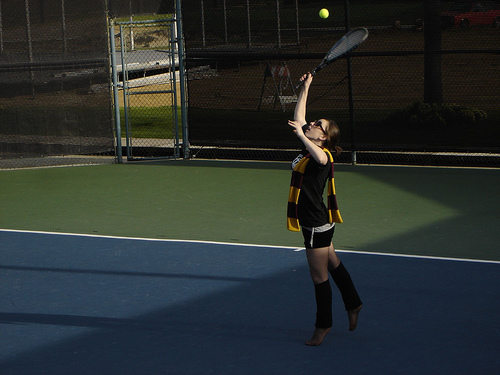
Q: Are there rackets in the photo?
A: Yes, there is a racket.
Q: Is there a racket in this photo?
A: Yes, there is a racket.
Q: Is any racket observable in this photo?
A: Yes, there is a racket.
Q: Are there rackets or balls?
A: Yes, there is a racket.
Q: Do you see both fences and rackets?
A: Yes, there are both a racket and a fence.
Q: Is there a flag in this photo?
A: No, there are no flags.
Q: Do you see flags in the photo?
A: No, there are no flags.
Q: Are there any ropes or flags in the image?
A: No, there are no flags or ropes.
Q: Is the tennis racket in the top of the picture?
A: Yes, the tennis racket is in the top of the image.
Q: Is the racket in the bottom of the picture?
A: No, the racket is in the top of the image.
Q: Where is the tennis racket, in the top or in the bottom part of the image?
A: The tennis racket is in the top of the image.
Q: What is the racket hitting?
A: The racket is hitting the tennis ball.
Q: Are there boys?
A: No, there are no boys.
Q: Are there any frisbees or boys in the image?
A: No, there are no boys or frisbees.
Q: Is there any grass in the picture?
A: Yes, there is grass.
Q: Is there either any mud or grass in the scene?
A: Yes, there is grass.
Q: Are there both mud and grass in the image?
A: No, there is grass but no mud.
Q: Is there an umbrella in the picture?
A: No, there are no umbrellas.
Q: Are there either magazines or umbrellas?
A: No, there are no umbrellas or magazines.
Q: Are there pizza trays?
A: No, there are no pizza trays.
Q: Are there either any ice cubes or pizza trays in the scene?
A: No, there are no pizza trays or ice cubes.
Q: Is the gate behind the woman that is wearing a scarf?
A: Yes, the gate is behind the woman.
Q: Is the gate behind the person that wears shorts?
A: Yes, the gate is behind the woman.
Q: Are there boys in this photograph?
A: No, there are no boys.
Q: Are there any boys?
A: No, there are no boys.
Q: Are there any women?
A: Yes, there is a woman.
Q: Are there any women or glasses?
A: Yes, there is a woman.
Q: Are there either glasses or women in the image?
A: Yes, there is a woman.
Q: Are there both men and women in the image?
A: No, there is a woman but no men.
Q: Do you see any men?
A: No, there are no men.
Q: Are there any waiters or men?
A: No, there are no men or waiters.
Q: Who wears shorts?
A: The woman wears shorts.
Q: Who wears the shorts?
A: The woman wears shorts.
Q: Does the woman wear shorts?
A: Yes, the woman wears shorts.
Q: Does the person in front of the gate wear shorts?
A: Yes, the woman wears shorts.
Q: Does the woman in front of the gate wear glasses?
A: No, the woman wears shorts.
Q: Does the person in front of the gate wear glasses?
A: No, the woman wears shorts.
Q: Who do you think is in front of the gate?
A: The woman is in front of the gate.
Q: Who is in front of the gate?
A: The woman is in front of the gate.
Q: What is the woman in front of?
A: The woman is in front of the gate.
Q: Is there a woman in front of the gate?
A: Yes, there is a woman in front of the gate.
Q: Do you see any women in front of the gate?
A: Yes, there is a woman in front of the gate.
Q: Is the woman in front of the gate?
A: Yes, the woman is in front of the gate.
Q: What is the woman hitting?
A: The woman is hitting the tennis ball.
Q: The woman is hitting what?
A: The woman is hitting the tennis ball.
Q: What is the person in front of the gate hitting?
A: The woman is hitting the tennis ball.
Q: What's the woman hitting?
A: The woman is hitting the tennis ball.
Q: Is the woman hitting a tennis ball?
A: Yes, the woman is hitting a tennis ball.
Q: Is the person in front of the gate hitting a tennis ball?
A: Yes, the woman is hitting a tennis ball.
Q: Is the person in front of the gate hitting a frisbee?
A: No, the woman is hitting a tennis ball.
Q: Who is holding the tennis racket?
A: The woman is holding the tennis racket.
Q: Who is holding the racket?
A: The woman is holding the tennis racket.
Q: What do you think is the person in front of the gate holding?
A: The woman is holding the tennis racket.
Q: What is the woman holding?
A: The woman is holding the tennis racket.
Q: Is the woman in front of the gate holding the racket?
A: Yes, the woman is holding the racket.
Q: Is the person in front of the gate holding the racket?
A: Yes, the woman is holding the racket.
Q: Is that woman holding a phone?
A: No, the woman is holding the racket.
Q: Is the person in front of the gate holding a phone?
A: No, the woman is holding the racket.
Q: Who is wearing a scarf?
A: The woman is wearing a scarf.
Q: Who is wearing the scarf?
A: The woman is wearing a scarf.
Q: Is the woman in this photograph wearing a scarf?
A: Yes, the woman is wearing a scarf.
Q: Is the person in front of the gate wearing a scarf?
A: Yes, the woman is wearing a scarf.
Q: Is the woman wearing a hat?
A: No, the woman is wearing a scarf.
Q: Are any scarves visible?
A: Yes, there is a scarf.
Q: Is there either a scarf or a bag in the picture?
A: Yes, there is a scarf.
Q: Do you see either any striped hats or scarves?
A: Yes, there is a striped scarf.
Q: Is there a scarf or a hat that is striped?
A: Yes, the scarf is striped.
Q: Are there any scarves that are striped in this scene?
A: Yes, there is a striped scarf.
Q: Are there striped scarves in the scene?
A: Yes, there is a striped scarf.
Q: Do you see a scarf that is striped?
A: Yes, there is a scarf that is striped.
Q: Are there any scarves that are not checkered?
A: Yes, there is a striped scarf.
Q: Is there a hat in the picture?
A: No, there are no hats.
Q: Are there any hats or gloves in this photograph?
A: No, there are no hats or gloves.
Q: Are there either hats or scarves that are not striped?
A: No, there is a scarf but it is striped.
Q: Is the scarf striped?
A: Yes, the scarf is striped.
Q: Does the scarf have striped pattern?
A: Yes, the scarf is striped.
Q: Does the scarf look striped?
A: Yes, the scarf is striped.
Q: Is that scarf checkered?
A: No, the scarf is striped.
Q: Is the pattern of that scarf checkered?
A: No, the scarf is striped.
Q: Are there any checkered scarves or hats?
A: No, there is a scarf but it is striped.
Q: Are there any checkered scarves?
A: No, there is a scarf but it is striped.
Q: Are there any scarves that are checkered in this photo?
A: No, there is a scarf but it is striped.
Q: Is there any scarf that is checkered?
A: No, there is a scarf but it is striped.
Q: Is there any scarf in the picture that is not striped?
A: No, there is a scarf but it is striped.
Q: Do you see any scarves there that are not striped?
A: No, there is a scarf but it is striped.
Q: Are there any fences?
A: Yes, there is a fence.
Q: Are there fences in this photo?
A: Yes, there is a fence.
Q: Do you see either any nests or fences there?
A: Yes, there is a fence.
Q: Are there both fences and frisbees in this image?
A: No, there is a fence but no frisbees.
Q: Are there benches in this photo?
A: No, there are no benches.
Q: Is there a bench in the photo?
A: No, there are no benches.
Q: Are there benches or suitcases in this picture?
A: No, there are no benches or suitcases.